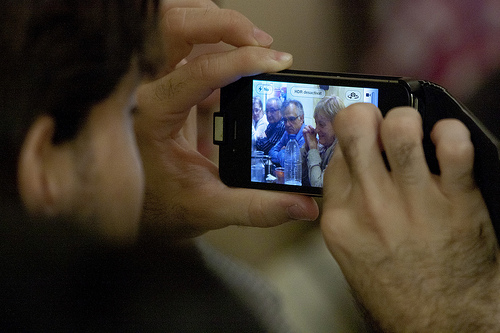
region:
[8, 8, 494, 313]
A person is using their cell phone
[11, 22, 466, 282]
A person is looking at a picture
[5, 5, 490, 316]
A person is saving a cell phone picture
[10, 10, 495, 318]
The person is trying to fix something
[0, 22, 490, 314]
The person is using his fingers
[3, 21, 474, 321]
The man is examining a photo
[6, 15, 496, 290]
The man is having great fun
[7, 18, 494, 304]
The man is in somebody's house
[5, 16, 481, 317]
The man is looking at his friends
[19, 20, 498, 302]
The man is enjoying his day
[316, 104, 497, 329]
a man's right hand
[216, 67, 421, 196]
taking a picture on a cell phone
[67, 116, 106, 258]
face stubble under dark hair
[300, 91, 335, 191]
blond lady wears a long sleeved top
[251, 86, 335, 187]
people sitting at a diner counter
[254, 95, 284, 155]
a man wearing a dark top looks on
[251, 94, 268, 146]
a woman wearing a white sweater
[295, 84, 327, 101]
a sign posted on the white wall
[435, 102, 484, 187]
a finger on hand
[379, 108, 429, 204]
a finger on hand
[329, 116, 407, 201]
a finger on hand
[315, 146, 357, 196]
a finger on hand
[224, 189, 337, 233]
a finger on hand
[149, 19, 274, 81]
a finger on hand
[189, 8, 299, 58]
a finger on hand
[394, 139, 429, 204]
dark hair on hand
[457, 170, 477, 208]
dark hair on hand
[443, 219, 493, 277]
dark hair on hand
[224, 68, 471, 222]
camera in the hand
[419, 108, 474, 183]
finger of the person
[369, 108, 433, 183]
finger of the person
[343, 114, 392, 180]
finger of the person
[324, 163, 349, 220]
finger of the person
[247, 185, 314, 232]
finger of the person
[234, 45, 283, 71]
finger of the person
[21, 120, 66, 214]
ear of the person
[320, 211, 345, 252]
knuckle of the person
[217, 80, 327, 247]
this is a cell phone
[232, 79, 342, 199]
the phone is an iphone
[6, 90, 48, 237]
this is an ear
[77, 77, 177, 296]
this is a head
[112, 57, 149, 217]
these are some eyelashes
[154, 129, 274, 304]
this is a hand